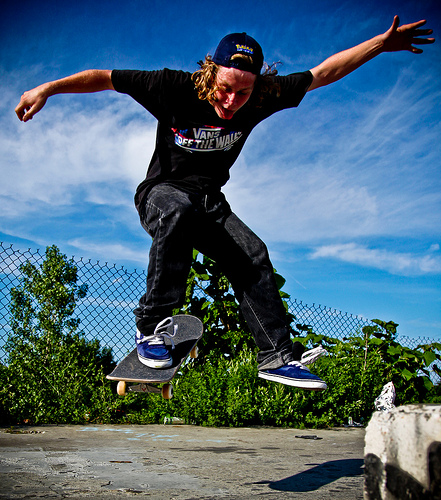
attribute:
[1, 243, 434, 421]
fence — metal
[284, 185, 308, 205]
grey cloud — small, patch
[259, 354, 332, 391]
shoe — blue, white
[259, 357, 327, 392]
shoe — blue, white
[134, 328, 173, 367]
shoe — blue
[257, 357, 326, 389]
shoe — blue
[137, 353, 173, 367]
sole — white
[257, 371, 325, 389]
sole — white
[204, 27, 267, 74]
baseball cap — backwards, black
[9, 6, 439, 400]
he — denim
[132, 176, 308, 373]
denim jeans — black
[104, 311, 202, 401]
skateboard — black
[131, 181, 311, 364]
jeans — black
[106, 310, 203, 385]
skateboard — black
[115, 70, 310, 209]
shirt — black, short sleeved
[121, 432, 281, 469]
ground — concrete, gray, small, patch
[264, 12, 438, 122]
arm — extended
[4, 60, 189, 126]
arm — extended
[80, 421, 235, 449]
writing — blue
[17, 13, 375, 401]
man — v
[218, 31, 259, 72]
hat — black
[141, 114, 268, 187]
shirt — black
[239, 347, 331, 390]
shoe — blue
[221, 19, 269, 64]
cap — blak